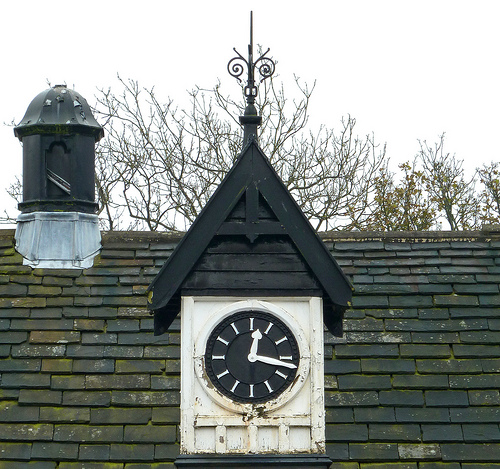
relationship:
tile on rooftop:
[90, 404, 151, 423] [0, 220, 491, 469]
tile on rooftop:
[62, 387, 107, 404] [0, 220, 491, 469]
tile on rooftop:
[85, 372, 150, 387] [0, 220, 491, 469]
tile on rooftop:
[70, 340, 139, 357] [0, 220, 491, 469]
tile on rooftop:
[368, 422, 422, 442] [0, 220, 491, 469]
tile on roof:
[106, 315, 138, 330] [18, 291, 160, 424]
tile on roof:
[72, 315, 106, 332] [18, 291, 160, 424]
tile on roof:
[77, 328, 120, 347] [18, 291, 160, 424]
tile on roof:
[41, 359, 73, 374] [18, 291, 160, 424]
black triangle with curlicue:
[143, 135, 369, 338] [224, 41, 276, 83]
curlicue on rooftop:
[224, 41, 276, 83] [12, 220, 491, 451]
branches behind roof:
[1, 34, 498, 245] [9, 2, 496, 464]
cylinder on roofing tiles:
[23, 195, 110, 265] [386, 237, 467, 372]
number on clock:
[259, 373, 279, 402] [189, 271, 313, 408]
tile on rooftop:
[367, 422, 424, 437] [0, 220, 491, 469]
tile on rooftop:
[123, 423, 177, 443] [0, 220, 491, 469]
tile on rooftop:
[77, 442, 112, 463] [0, 220, 491, 469]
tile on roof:
[37, 358, 72, 372] [21, 311, 147, 433]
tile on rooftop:
[81, 333, 118, 344] [0, 220, 491, 469]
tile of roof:
[376, 260, 477, 323] [21, 100, 463, 467]